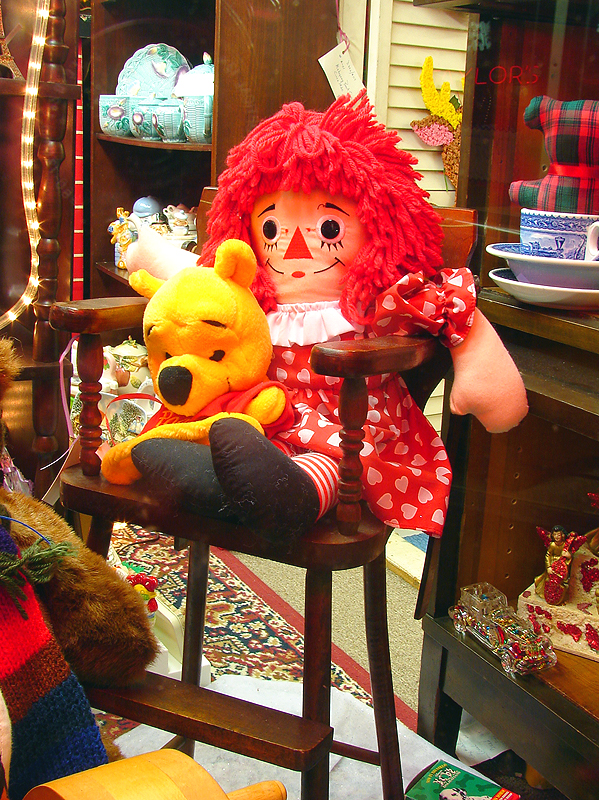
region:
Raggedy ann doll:
[115, 86, 529, 541]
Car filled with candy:
[442, 577, 559, 680]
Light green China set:
[96, 39, 214, 146]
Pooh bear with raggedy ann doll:
[92, 85, 530, 540]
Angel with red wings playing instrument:
[530, 520, 594, 607]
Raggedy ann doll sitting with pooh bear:
[98, 87, 529, 543]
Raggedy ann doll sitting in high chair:
[47, 87, 531, 798]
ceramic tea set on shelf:
[94, 37, 212, 145]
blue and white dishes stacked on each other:
[488, 201, 597, 312]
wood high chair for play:
[52, 183, 478, 798]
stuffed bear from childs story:
[87, 239, 291, 503]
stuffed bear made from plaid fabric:
[507, 91, 597, 221]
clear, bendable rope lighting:
[0, 0, 52, 329]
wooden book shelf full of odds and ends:
[81, 1, 347, 448]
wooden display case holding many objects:
[421, 3, 596, 790]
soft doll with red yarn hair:
[122, 99, 529, 547]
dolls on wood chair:
[51, 88, 530, 798]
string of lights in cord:
[0, 1, 50, 327]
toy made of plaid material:
[507, 94, 596, 212]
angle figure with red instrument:
[536, 526, 584, 603]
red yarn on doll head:
[198, 88, 443, 319]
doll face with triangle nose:
[252, 192, 361, 302]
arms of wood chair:
[45, 295, 436, 535]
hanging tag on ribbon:
[316, 1, 366, 106]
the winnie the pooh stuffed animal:
[101, 240, 296, 485]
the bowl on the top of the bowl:
[520, 205, 598, 259]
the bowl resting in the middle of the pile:
[483, 242, 598, 287]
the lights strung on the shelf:
[0, 1, 50, 328]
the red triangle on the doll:
[283, 226, 314, 261]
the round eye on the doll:
[315, 213, 347, 251]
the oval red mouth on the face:
[289, 270, 306, 277]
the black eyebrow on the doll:
[325, 203, 349, 218]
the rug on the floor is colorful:
[110, 526, 417, 730]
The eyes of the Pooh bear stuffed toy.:
[152, 349, 230, 365]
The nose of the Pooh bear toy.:
[152, 362, 197, 408]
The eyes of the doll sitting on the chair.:
[256, 214, 348, 241]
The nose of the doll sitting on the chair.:
[285, 223, 310, 262]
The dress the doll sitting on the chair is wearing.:
[234, 259, 477, 534]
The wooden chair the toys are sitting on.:
[38, 190, 477, 796]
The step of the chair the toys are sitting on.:
[58, 632, 330, 769]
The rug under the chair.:
[76, 480, 435, 788]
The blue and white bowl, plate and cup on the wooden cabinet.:
[484, 204, 596, 306]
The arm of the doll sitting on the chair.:
[449, 308, 526, 438]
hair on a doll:
[207, 97, 444, 327]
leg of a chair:
[362, 559, 407, 797]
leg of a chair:
[301, 561, 328, 797]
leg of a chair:
[174, 545, 208, 756]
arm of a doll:
[438, 317, 521, 429]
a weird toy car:
[455, 585, 550, 674]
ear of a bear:
[217, 243, 251, 284]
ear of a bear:
[131, 271, 158, 289]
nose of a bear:
[154, 366, 188, 402]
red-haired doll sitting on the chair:
[124, 94, 529, 550]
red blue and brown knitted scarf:
[0, 525, 106, 797]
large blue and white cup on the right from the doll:
[519, 207, 597, 261]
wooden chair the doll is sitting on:
[47, 184, 480, 798]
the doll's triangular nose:
[283, 223, 313, 260]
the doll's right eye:
[260, 215, 282, 244]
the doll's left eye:
[318, 215, 344, 243]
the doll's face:
[253, 188, 357, 296]